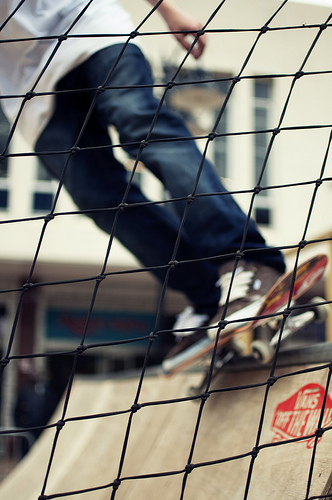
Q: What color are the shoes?
A: Brown.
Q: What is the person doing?
A: Skateboarding.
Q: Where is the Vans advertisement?
A: On the skate ramp.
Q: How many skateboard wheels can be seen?
A: Three.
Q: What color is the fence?
A: Black.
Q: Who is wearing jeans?
A: The skateboarder.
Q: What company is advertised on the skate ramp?
A: Vans.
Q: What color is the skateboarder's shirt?
A: White.